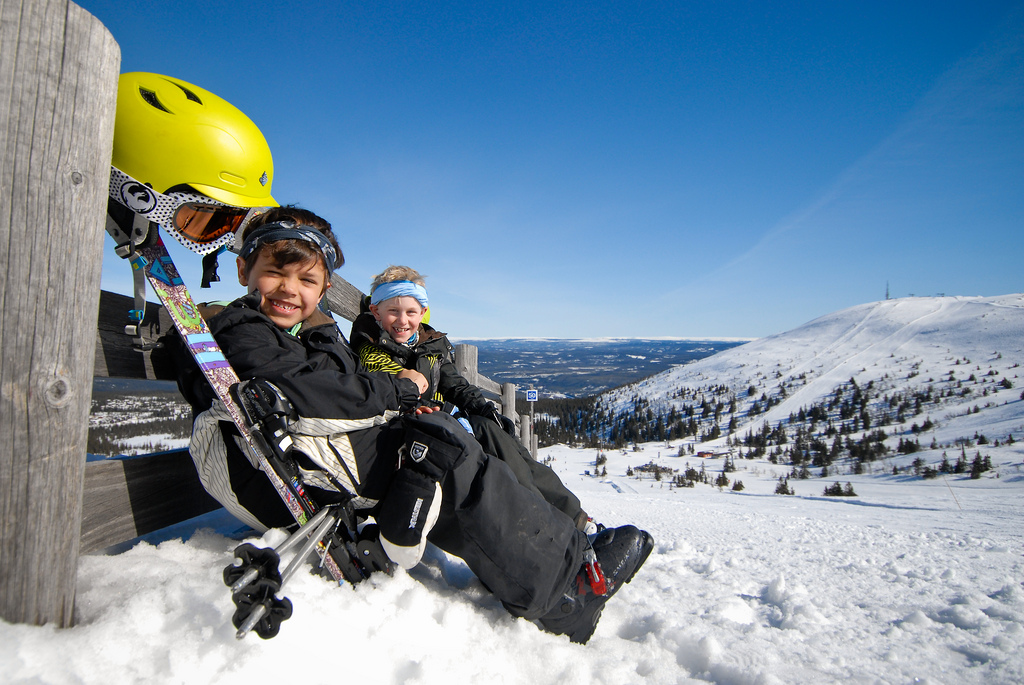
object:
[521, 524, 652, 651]
boot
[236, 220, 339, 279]
bandanna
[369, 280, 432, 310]
bandanna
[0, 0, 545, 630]
fence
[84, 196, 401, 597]
ski pole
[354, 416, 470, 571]
gloves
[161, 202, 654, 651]
boy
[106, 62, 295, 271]
helmet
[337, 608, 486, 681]
snow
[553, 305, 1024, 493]
hillside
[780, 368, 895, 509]
trees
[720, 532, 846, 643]
tracks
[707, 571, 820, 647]
snow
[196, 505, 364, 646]
ski poles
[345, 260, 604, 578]
boy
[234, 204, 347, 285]
hair